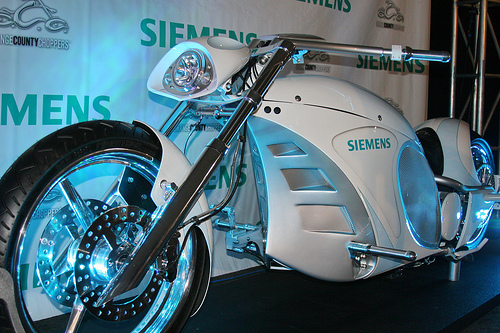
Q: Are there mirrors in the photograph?
A: No, there are no mirrors.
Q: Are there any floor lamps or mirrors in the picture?
A: No, there are no mirrors or floor lamps.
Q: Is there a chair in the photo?
A: No, there are no chairs.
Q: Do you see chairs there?
A: No, there are no chairs.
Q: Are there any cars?
A: No, there are no cars.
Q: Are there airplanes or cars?
A: No, there are no cars or airplanes.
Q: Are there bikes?
A: Yes, there is a bike.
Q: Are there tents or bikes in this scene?
A: Yes, there is a bike.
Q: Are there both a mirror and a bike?
A: No, there is a bike but no mirrors.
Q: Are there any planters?
A: No, there are no planters.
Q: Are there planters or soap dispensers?
A: No, there are no planters or soap dispensers.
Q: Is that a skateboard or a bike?
A: That is a bike.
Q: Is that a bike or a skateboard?
A: That is a bike.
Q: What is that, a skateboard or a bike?
A: That is a bike.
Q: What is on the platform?
A: The bike is on the platform.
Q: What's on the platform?
A: The bike is on the platform.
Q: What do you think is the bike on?
A: The bike is on the platform.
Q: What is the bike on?
A: The bike is on the platform.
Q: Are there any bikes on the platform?
A: Yes, there is a bike on the platform.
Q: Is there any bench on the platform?
A: No, there is a bike on the platform.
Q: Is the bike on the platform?
A: Yes, the bike is on the platform.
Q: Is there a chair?
A: No, there are no chairs.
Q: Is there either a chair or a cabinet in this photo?
A: No, there are no chairs or cabinets.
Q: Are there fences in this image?
A: No, there are no fences.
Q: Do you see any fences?
A: No, there are no fences.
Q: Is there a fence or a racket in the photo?
A: No, there are no fences or rackets.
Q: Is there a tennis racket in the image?
A: No, there are no rackets.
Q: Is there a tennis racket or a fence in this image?
A: No, there are no rackets or fences.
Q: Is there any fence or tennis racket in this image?
A: No, there are no rackets or fences.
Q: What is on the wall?
A: The logo is on the wall.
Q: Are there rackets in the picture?
A: No, there are no rackets.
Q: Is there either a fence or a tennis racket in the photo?
A: No, there are no rackets or fences.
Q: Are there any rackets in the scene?
A: No, there are no rackets.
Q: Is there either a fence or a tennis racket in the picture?
A: No, there are no rackets or fences.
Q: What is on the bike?
A: The logo is on the bike.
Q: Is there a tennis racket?
A: No, there are no rackets.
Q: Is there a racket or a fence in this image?
A: No, there are no rackets or fences.